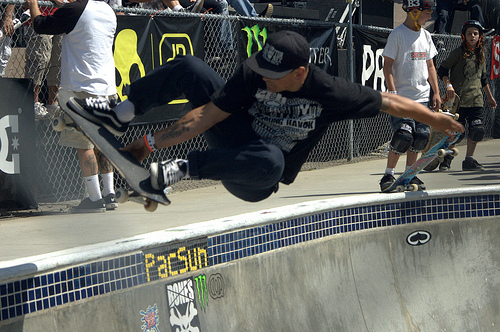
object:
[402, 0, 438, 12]
helmet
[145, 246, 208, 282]
letter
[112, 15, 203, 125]
advertisements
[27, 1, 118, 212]
guy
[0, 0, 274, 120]
spectators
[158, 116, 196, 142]
tattoo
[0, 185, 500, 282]
edge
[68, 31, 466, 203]
man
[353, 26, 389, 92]
signs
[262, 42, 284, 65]
signs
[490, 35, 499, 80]
signs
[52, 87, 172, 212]
skateboard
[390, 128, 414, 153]
black kneepad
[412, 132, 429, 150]
black kneepad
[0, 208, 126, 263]
ground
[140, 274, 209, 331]
monster advertisement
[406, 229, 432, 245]
spade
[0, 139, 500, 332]
skate arena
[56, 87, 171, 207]
board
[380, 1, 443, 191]
person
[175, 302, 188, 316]
black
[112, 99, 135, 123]
white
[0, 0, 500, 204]
background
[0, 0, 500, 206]
fence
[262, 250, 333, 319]
part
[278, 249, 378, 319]
part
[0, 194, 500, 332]
surface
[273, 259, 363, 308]
part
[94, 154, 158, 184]
part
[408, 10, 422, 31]
straps